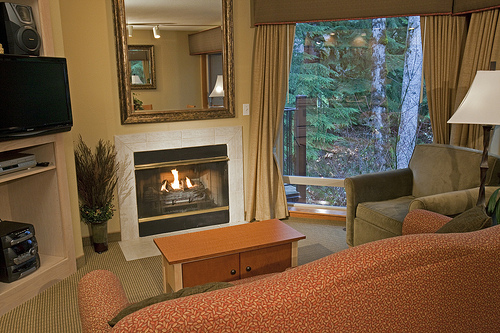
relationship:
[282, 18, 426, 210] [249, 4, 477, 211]
outdoor from window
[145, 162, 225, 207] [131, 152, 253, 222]
logs in fire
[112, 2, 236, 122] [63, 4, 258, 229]
mirror on wall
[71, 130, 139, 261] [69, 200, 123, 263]
plant in vase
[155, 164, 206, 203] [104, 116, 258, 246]
fire in fireplace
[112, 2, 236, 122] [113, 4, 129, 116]
mirror in frame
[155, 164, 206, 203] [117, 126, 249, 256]
fire in fire place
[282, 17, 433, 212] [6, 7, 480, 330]
window in living room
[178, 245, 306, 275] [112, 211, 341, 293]
cupboards in coffee table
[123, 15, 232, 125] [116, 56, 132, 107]
mirror in frame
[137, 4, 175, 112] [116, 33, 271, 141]
reflection in mirror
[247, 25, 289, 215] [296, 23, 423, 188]
tan curtain in window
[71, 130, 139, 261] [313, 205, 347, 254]
plant on floor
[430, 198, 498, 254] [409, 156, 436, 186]
pillow on couch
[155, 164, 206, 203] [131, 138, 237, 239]
fire in fireplace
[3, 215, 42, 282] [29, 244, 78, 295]
stereo on shelf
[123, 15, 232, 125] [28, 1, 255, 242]
mirror on wall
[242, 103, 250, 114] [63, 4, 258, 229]
light switch on wall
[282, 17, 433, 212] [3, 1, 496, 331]
window in room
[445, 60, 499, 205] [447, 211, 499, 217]
lamp on top of table